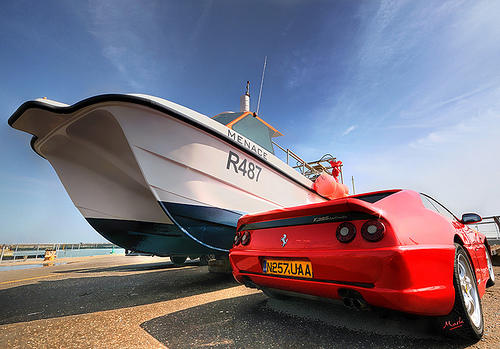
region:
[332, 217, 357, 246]
a red and white tail light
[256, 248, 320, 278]
a yellow license plate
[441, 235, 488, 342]
a black tire on the car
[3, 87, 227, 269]
the bow of a ship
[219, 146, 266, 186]
black letters on the boat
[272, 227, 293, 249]
a logo on the car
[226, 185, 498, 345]
a red sports car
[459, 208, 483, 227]
a side view mirror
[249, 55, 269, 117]
an antenna on the boat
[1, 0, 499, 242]
a blue and white sky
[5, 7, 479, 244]
a blue sky with some clouds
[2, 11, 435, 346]
a scene outside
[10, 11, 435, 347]
a clear sunny day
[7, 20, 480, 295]
scene happening during the day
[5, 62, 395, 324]
a white and blue yacht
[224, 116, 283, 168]
a word on the boat that says MENACE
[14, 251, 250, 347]
Gray dock next to the water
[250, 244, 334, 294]
a yellow license that says N257UAA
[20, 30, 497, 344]
two vehicles are here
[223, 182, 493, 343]
A red car parked beside a boat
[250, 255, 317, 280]
A yellow license plate with black writing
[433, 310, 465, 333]
A red watermark over the tire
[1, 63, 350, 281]
A large white boat on land, beside the car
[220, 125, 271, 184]
Writing on the boat, saying "Menace R487"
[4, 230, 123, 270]
The water beside the dock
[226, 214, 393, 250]
Round stoplights on the back of the car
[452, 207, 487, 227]
The side mirror of the car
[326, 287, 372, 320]
Black exhaust pipes on the car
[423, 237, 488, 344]
The black tire with shiny metal rims on the car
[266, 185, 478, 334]
this is a car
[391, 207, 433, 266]
the car is red in color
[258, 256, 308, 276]
this is the number plate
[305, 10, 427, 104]
this is the sky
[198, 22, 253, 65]
the sky is blue in color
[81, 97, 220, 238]
this is a boat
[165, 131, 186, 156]
the boat is white in color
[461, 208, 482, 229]
this is a side mirror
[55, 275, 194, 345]
this is the ground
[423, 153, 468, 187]
these are the clouds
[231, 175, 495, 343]
A red, parked car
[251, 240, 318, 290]
Yellow and black license plate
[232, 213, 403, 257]
Four round lights on the back of the car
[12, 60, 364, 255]
White and blue boat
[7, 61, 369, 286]
The boat is parked on the asphalt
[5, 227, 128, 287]
The street is next to the water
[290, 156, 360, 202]
The boat has orange buoys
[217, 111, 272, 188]
The letters MENACE R487 are on the side of the boat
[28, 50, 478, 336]
The boat is parked next to the car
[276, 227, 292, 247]
The car has a silver logo on the back